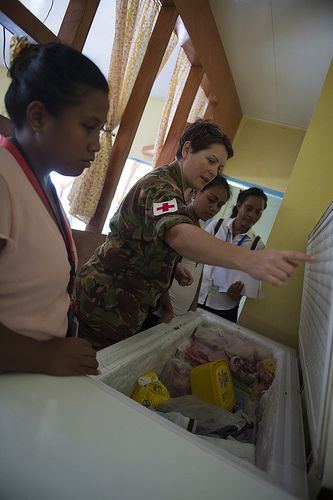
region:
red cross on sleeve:
[150, 194, 185, 219]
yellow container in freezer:
[185, 354, 244, 415]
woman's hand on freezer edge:
[39, 329, 103, 385]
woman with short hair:
[170, 110, 238, 191]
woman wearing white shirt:
[205, 212, 265, 320]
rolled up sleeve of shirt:
[149, 215, 192, 250]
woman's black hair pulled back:
[4, 41, 100, 128]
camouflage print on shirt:
[101, 247, 147, 306]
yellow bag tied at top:
[127, 365, 171, 415]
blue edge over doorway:
[231, 178, 283, 196]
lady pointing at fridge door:
[55, 90, 319, 495]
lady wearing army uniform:
[56, 97, 262, 376]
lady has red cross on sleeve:
[145, 187, 188, 231]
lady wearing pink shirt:
[9, 20, 125, 401]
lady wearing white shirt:
[178, 137, 262, 341]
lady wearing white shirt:
[150, 155, 223, 339]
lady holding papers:
[212, 234, 281, 321]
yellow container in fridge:
[178, 348, 262, 432]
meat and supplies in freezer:
[116, 325, 275, 475]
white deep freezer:
[1, 189, 331, 498]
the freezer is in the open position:
[3, 204, 329, 496]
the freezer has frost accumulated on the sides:
[92, 311, 275, 474]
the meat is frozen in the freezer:
[161, 314, 273, 397]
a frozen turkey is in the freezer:
[126, 369, 168, 408]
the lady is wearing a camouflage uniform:
[66, 115, 235, 335]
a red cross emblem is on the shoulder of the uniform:
[139, 183, 191, 248]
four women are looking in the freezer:
[1, 32, 269, 333]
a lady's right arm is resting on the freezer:
[0, 316, 108, 393]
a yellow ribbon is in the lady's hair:
[3, 32, 41, 71]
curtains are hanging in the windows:
[56, 1, 222, 228]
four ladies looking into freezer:
[0, 24, 293, 492]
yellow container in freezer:
[181, 346, 254, 429]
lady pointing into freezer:
[44, 113, 320, 382]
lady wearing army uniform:
[69, 100, 241, 335]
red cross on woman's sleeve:
[146, 192, 186, 232]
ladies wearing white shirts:
[137, 175, 283, 341]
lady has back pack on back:
[211, 209, 278, 289]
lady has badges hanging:
[6, 149, 106, 365]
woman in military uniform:
[82, 117, 235, 336]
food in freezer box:
[156, 347, 263, 416]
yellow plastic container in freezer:
[183, 358, 236, 418]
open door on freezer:
[297, 216, 326, 430]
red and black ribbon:
[4, 139, 84, 272]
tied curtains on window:
[94, 63, 140, 168]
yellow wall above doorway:
[243, 117, 291, 189]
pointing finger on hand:
[245, 243, 318, 289]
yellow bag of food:
[130, 369, 169, 409]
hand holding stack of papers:
[207, 269, 265, 308]